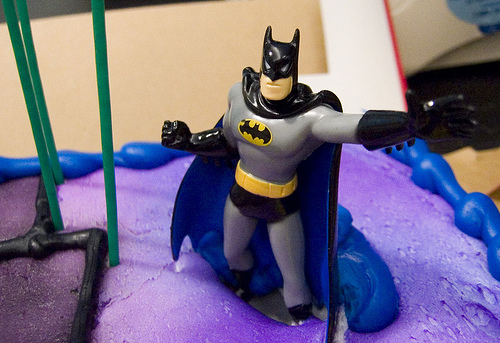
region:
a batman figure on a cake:
[143, 14, 476, 331]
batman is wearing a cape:
[158, 2, 353, 334]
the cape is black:
[156, 37, 378, 332]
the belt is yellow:
[193, 149, 308, 208]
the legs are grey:
[183, 183, 315, 315]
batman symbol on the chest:
[215, 95, 282, 152]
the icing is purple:
[363, 169, 443, 338]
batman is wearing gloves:
[134, 76, 488, 189]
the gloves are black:
[119, 84, 482, 231]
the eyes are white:
[242, 50, 301, 80]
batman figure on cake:
[171, 57, 441, 327]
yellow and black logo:
[231, 112, 281, 145]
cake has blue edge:
[22, 145, 495, 286]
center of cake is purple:
[13, 166, 206, 329]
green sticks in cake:
[15, 2, 137, 265]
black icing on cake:
[12, 198, 132, 341]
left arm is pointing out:
[165, 82, 442, 201]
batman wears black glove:
[348, 89, 443, 167]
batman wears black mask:
[252, 7, 342, 131]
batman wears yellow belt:
[228, 150, 333, 219]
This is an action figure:
[198, 36, 344, 301]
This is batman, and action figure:
[227, 41, 422, 333]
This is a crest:
[211, 100, 316, 172]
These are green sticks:
[12, 21, 167, 299]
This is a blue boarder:
[423, 147, 496, 238]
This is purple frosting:
[406, 267, 477, 339]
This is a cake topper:
[133, 45, 338, 330]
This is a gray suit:
[185, 95, 333, 336]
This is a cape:
[137, 185, 252, 286]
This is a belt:
[215, 153, 358, 232]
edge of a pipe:
[110, 230, 128, 256]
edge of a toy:
[284, 261, 295, 280]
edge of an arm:
[373, 122, 386, 127]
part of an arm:
[449, 111, 456, 128]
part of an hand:
[336, 124, 353, 133]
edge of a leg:
[241, 243, 251, 268]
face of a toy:
[268, 60, 290, 100]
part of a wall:
[134, 71, 143, 92]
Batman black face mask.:
[257, 26, 304, 102]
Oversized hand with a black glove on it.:
[355, 97, 492, 149]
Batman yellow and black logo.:
[237, 118, 274, 149]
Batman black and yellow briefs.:
[230, 160, 300, 224]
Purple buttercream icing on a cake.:
[122, 297, 232, 334]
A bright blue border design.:
[400, 151, 498, 281]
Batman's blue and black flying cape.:
[170, 64, 345, 333]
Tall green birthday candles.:
[6, 3, 73, 229]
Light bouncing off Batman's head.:
[267, 40, 284, 62]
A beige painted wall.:
[127, 7, 259, 59]